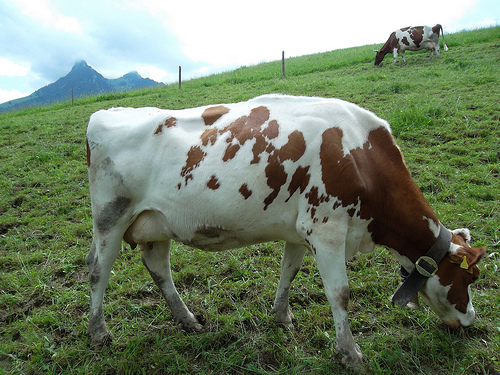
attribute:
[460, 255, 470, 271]
tag — yellow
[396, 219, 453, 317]
collar — is leather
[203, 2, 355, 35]
sky — cloudy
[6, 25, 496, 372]
ground — slopy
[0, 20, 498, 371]
hillside — steep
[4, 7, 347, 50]
sky — cloudy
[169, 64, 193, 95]
fence post — is large, is wooden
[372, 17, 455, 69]
cow — brown, white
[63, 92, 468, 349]
cow — white and brown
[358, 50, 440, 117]
grass — green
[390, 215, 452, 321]
collar — leather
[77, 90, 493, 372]
cow — is brown, is white, brown, white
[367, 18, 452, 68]
cow — is medium sized, is brown, is white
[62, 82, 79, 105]
fence — is large, is wooden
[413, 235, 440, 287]
collar — black, leather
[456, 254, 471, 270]
livestock tag — is yellow, is plastic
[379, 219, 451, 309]
collar — silver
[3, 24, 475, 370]
grass — green